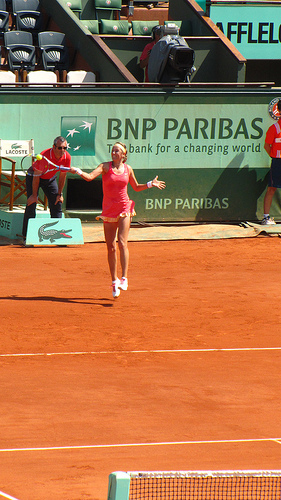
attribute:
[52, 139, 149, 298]
player — blonde, in air, woman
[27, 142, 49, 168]
ball — yellow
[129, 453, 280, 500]
net — tennis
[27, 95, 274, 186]
logo — ad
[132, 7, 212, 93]
cameraman — filming, recording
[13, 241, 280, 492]
court — orange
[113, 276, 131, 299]
shoes — white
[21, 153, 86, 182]
racket — white, tennis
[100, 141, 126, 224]
dress — red, pink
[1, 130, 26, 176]
symbol — alligator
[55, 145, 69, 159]
glasses — dark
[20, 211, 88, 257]
alligator — painted, logo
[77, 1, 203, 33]
seats — empty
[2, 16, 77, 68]
seats — black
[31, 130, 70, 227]
man — watching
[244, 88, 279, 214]
person — standing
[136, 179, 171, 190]
fingers — spread